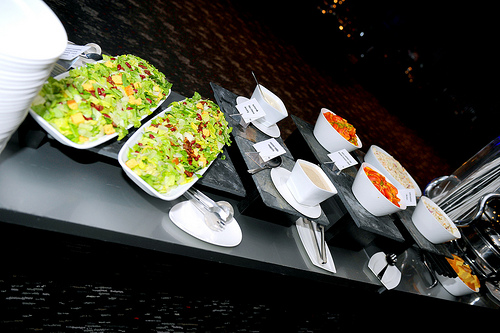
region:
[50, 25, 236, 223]
salads on the plates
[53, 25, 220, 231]
salads on the plates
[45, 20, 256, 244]
salads on the plates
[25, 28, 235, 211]
salads on the plates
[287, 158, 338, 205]
square bowl of white soup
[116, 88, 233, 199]
long serving platter of salad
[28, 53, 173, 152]
long serving platter of salad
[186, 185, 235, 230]
small silver metal tongs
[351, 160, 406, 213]
white bowl of strawberries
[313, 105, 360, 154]
white bowl of strawberries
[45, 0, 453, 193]
black and white patterned carpet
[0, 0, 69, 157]
stack of white plates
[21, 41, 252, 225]
the bowls are mixed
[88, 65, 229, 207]
the bowls have veggies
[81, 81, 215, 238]
the bowls are green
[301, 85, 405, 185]
the veggies are red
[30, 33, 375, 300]
the counter is gray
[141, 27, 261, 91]
the carpet is black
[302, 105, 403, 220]
the bowls are white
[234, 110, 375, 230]
these are dipping sauces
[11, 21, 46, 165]
the bowls are stacked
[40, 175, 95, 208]
a counter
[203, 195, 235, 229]
eating utensils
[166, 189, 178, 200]
the dish is white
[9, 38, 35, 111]
a stack of plates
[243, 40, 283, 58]
the floor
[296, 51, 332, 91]
the carpet on the floor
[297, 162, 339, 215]
a bowl on a table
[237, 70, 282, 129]
a bowl on a table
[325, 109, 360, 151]
a bowl on a table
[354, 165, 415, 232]
a bowl on a table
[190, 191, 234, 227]
tongs on the table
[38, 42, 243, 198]
long platters on the table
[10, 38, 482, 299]
table the plates are on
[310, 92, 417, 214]
bowls of orange food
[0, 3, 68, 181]
white plates stacked on the table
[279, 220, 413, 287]
white napkins on the table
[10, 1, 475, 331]
carpeting in the room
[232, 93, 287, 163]
white cards with black text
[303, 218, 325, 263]
the tongs are silver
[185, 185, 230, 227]
the tongs are silver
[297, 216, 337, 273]
the tongs on the plate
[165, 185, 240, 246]
the tongs on the plate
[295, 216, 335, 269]
the tongs on the plate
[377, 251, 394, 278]
the spoon is silver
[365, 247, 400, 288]
the spoon is on the plate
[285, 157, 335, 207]
the bowl is white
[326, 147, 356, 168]
the paper is white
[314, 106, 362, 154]
the bowl is white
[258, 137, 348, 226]
white cup of coffee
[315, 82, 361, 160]
white bowl of food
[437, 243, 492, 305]
white bowl of food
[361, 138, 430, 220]
white bowl of food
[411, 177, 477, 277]
white bowl of food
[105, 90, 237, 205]
long white platter of salad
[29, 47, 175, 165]
white long platter of salad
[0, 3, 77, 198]
stack of white plates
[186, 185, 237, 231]
Silver tongs sitting on a white plate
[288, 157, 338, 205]
Cup sitting on a white plate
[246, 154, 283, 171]
Spoon next to a white plate